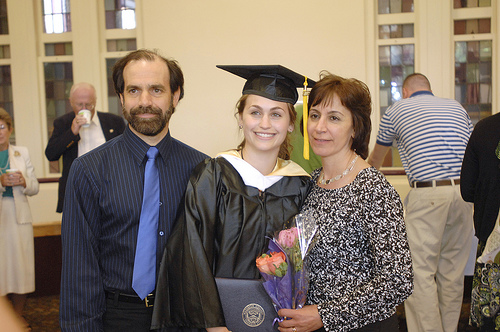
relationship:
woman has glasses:
[1, 108, 41, 317] [1, 121, 6, 133]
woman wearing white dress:
[1, 108, 41, 317] [0, 147, 42, 295]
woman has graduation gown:
[149, 65, 320, 332] [150, 153, 311, 332]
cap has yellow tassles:
[215, 65, 318, 161] [302, 76, 312, 160]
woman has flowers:
[256, 76, 413, 331] [254, 226, 310, 315]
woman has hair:
[256, 76, 413, 331] [302, 73, 372, 161]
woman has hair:
[1, 108, 41, 317] [0, 105, 13, 134]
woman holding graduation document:
[149, 65, 320, 332] [217, 276, 281, 331]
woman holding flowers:
[256, 76, 413, 331] [254, 226, 310, 315]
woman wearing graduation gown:
[149, 65, 320, 332] [150, 153, 311, 332]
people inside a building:
[0, 49, 499, 332] [0, 2, 500, 331]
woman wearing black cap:
[149, 65, 320, 332] [215, 65, 318, 161]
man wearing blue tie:
[57, 47, 211, 330] [132, 142, 160, 301]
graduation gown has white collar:
[150, 153, 311, 332] [217, 146, 313, 191]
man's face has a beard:
[113, 50, 183, 137] [120, 102, 174, 135]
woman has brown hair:
[256, 76, 413, 331] [302, 73, 372, 161]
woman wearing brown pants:
[256, 76, 413, 331] [316, 316, 396, 331]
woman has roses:
[256, 76, 413, 331] [254, 226, 310, 315]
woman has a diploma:
[149, 65, 320, 332] [217, 276, 281, 331]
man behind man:
[46, 82, 126, 217] [57, 47, 211, 330]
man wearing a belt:
[57, 47, 211, 330] [104, 288, 160, 308]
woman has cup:
[1, 108, 41, 317] [5, 166, 19, 185]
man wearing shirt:
[44, 32, 237, 330] [376, 90, 475, 183]